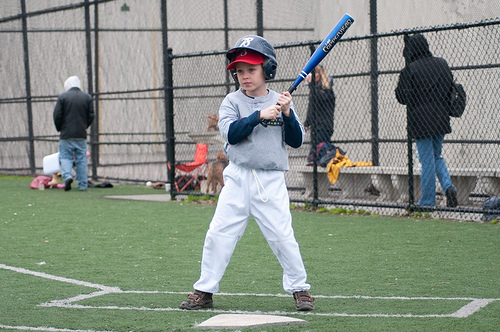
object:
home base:
[195, 309, 306, 327]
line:
[0, 262, 113, 290]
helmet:
[226, 34, 278, 83]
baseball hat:
[227, 50, 264, 70]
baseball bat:
[261, 12, 354, 127]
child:
[29, 176, 65, 189]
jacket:
[326, 147, 373, 184]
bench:
[297, 165, 497, 206]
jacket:
[395, 30, 454, 139]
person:
[396, 32, 459, 208]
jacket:
[53, 87, 94, 139]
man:
[53, 75, 96, 192]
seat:
[168, 142, 211, 193]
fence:
[2, 1, 497, 221]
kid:
[179, 33, 313, 310]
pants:
[193, 160, 314, 293]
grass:
[2, 173, 500, 329]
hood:
[64, 75, 81, 91]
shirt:
[218, 87, 305, 173]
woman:
[303, 63, 335, 165]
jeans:
[311, 132, 333, 150]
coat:
[303, 76, 336, 144]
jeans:
[57, 137, 89, 191]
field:
[0, 173, 499, 330]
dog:
[205, 150, 229, 194]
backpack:
[450, 81, 466, 117]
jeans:
[414, 134, 458, 207]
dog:
[206, 112, 219, 131]